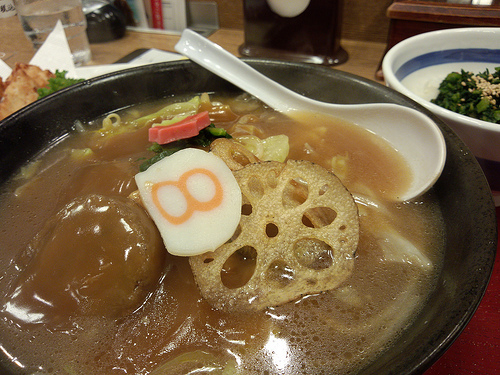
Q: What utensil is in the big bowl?
A: A spoon.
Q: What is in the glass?
A: Water.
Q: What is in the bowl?
A: Soup.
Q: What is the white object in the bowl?
A: A spoon.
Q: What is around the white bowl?
A: A blue stripe.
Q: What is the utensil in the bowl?
A: Spoon.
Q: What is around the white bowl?
A: A blue stripe.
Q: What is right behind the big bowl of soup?
A: An egg roll.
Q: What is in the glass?
A: Water.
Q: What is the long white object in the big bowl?
A: A spoon.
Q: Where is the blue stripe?
A: In the white bowl.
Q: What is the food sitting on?
A: A table.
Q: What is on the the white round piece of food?
A: The number 8.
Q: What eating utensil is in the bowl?
A: White ceramic spoon.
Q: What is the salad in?
A: A small white bowl with a blue stripe.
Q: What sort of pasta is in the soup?
A: Noodles.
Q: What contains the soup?
A: A shallow black bowl.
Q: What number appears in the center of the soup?
A: The number 8.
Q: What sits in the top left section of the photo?
A: A piece of toasted bread.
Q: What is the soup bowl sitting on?
A: A wooden table.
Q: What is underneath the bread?
A: A napkin.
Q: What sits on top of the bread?
A: A sprig of parsley.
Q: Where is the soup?
A: In the bowl.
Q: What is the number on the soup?
A: 8.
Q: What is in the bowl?
A: A soup.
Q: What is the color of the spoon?
A: White.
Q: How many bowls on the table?
A: Two.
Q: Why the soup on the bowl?
A: So it won't spill.